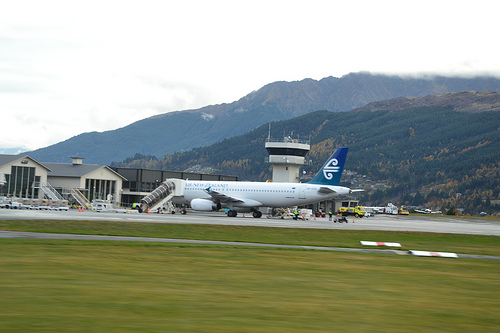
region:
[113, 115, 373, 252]
this is a plane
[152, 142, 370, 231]
body of the plane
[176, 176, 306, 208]
row of windows on the plane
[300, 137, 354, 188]
blue tail on the plane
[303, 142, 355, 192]
white design on tail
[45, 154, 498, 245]
plane is on the tarmac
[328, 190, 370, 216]
this is a yellow truck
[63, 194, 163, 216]
orange cones on the ground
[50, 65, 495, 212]
mountain side in the backgrounds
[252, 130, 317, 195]
tower behind the plane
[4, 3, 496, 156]
light in daytime sky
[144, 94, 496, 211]
trees on side of mountain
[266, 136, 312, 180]
air traffic control tower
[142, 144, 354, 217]
side of parked plane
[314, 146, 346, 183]
white emblem on plane tail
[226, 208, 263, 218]
wheels of landing gear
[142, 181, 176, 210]
cover over boarding ramp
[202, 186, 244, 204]
wing on side of plane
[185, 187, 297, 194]
windows on side of plane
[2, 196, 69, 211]
vehicles on airport tarmac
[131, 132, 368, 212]
plane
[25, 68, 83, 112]
white clouds in blue sky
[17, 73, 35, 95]
white clouds in blue sky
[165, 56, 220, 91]
white clouds in blue sky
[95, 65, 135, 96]
white clouds in blue sky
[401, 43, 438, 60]
white clouds in blue sky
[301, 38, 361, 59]
white clouds in blue sky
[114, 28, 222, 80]
white clouds in blue sky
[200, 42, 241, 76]
white clouds in blue sky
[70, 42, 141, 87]
white clouds in blue sky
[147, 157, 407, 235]
a large blue and white plae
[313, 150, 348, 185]
white design on tail of plane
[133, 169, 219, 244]
stairway leading to plane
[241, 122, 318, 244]
a white and black control tower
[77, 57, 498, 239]
a mountain in the background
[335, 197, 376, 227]
a yellow truck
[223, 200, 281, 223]
wheels under middle of plance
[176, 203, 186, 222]
wheel on front of plane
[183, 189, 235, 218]
an engine under the wing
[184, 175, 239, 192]
blue letters on the plane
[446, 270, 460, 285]
part of a garden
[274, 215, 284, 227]
part of a wheel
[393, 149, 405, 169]
part of a hill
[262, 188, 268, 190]
edge of a plane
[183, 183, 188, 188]
part of a grass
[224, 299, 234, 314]
edge of a grass